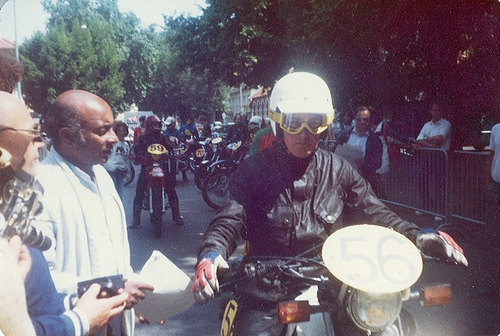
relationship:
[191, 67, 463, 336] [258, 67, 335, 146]
biker wears helmet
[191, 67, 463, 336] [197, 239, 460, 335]
biker on motorcycle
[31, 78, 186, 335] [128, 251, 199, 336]
man holding paper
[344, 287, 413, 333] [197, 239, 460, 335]
light on motorcycle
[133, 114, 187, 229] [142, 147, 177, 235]
person on bike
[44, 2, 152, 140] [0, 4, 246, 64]
tree touches sky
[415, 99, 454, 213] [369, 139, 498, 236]
man behind fence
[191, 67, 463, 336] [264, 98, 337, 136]
biker wears goggles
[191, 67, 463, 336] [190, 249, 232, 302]
biker wears glove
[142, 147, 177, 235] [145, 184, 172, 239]
bike has wheel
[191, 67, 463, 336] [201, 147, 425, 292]
biker wears jacket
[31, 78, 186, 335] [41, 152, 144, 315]
man wears shirt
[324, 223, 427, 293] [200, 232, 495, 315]
circle on handlebars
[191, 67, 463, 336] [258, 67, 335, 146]
biker with helmet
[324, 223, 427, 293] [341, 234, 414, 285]
circle with 56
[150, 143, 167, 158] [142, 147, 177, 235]
59 on bike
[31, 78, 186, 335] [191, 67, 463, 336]
man talking to biker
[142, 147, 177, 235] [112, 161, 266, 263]
bike in shade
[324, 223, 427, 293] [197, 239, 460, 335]
circle on motorcycle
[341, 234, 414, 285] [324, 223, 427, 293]
56 on circle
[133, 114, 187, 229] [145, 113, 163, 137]
person wears helmet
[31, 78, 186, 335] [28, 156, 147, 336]
man wearing jacket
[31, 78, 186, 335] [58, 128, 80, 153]
man has ear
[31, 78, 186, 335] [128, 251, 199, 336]
man hold paper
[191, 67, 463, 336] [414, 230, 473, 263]
biker wears glove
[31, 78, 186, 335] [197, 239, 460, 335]
man next to motorcycle